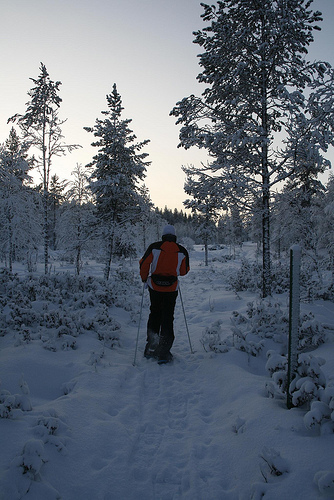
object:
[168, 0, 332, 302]
tree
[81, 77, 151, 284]
tree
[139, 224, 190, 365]
skier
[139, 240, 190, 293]
jacket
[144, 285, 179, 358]
pants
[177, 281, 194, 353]
ski pole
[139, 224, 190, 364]
person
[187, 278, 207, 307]
snow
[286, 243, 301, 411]
post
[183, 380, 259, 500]
trail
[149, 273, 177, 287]
fanny pack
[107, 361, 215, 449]
path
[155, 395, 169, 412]
footprint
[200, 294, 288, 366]
shrub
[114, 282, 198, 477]
tracks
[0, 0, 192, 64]
sky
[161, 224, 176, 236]
cap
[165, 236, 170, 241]
pompom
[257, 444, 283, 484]
grass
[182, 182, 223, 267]
pine trees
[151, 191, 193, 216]
distance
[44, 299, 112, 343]
brush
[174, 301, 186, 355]
uphill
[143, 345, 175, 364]
skiing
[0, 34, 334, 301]
forest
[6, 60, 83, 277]
trees